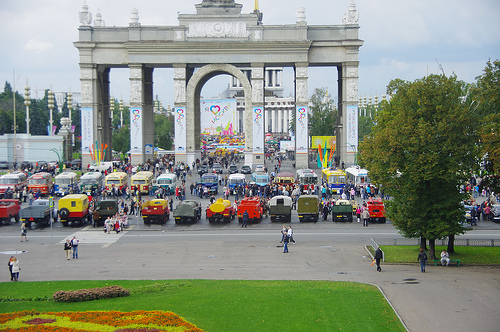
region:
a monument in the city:
[61, 6, 370, 178]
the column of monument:
[334, 63, 366, 171]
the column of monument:
[290, 62, 317, 176]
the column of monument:
[119, 67, 159, 164]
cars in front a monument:
[1, 4, 395, 244]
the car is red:
[234, 188, 267, 226]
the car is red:
[358, 193, 389, 225]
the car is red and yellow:
[52, 188, 90, 225]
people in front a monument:
[3, 0, 414, 286]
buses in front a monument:
[26, 11, 188, 190]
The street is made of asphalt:
[122, 233, 264, 268]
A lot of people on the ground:
[6, 215, 458, 284]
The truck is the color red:
[233, 188, 268, 221]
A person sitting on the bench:
[432, 245, 469, 271]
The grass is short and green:
[195, 285, 369, 328]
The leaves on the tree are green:
[411, 108, 459, 198]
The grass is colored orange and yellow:
[17, 308, 187, 328]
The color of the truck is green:
[296, 188, 320, 223]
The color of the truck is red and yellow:
[203, 193, 234, 228]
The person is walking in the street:
[368, 241, 395, 273]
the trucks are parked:
[21, 183, 386, 228]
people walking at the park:
[269, 221, 304, 256]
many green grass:
[191, 288, 312, 312]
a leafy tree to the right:
[369, 83, 473, 236]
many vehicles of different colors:
[6, 167, 384, 230]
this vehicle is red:
[237, 197, 261, 215]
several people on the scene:
[7, 220, 453, 283]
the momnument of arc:
[78, 12, 354, 167]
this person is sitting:
[439, 247, 450, 264]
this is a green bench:
[437, 255, 460, 265]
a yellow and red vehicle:
[59, 195, 85, 222]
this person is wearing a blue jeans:
[73, 245, 78, 257]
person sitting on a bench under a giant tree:
[429, 245, 462, 269]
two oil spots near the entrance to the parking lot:
[400, 274, 422, 285]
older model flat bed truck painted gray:
[15, 194, 59, 231]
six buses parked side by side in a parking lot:
[20, 166, 180, 197]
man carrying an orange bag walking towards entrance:
[368, 240, 386, 272]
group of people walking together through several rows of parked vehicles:
[102, 211, 130, 233]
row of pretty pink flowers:
[49, 280, 130, 303]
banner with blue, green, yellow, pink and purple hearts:
[250, 102, 266, 157]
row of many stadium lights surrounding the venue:
[17, 85, 398, 116]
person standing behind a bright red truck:
[232, 193, 266, 230]